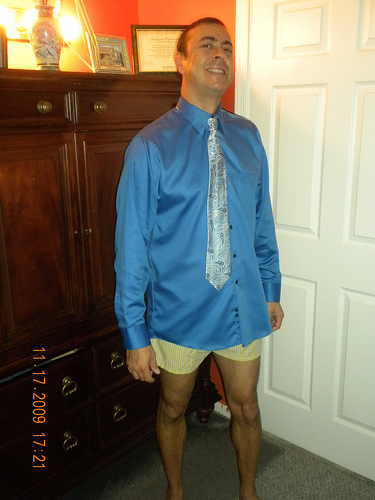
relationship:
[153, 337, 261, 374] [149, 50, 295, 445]
shorts on man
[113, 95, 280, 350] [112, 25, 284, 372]
shirt on man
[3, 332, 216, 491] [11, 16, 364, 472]
drawers in room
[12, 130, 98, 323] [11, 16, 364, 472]
cabinet in room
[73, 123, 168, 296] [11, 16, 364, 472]
cabinet in room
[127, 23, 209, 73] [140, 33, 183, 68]
paper in glass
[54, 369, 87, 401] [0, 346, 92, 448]
handle on cabinets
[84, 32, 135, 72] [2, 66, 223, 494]
image on top of cabinets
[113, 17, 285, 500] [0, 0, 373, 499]
man standing in room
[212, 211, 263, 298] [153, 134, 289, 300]
buttons on top of shirt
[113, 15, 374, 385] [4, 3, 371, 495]
man standing in bedroom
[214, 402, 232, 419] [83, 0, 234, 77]
base under wall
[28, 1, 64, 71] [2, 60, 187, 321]
lamp on dresser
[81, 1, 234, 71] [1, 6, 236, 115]
wall of bedroom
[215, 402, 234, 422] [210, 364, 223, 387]
base under wall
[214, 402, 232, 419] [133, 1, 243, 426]
base under wall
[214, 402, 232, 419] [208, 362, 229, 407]
base under wall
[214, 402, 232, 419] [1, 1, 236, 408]
base under wall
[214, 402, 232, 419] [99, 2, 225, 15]
base under wall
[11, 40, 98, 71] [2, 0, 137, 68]
board under wall